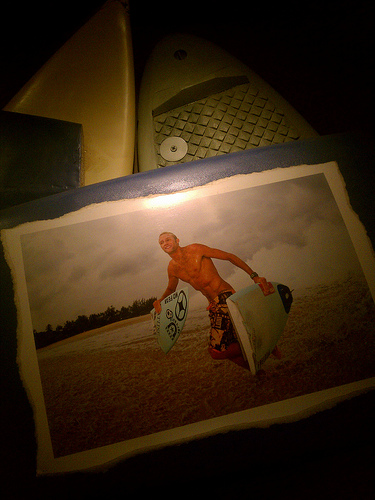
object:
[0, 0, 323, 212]
board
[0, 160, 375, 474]
photo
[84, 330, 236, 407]
ground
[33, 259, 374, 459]
ground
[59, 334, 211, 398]
beach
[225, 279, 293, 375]
board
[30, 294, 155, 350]
tree grove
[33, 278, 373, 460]
sand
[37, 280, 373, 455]
ground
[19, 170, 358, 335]
sky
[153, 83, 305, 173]
diamond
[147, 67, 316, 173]
board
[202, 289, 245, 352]
trunks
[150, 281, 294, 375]
surf board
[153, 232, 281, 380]
man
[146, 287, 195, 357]
piece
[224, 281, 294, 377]
piece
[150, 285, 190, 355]
designs